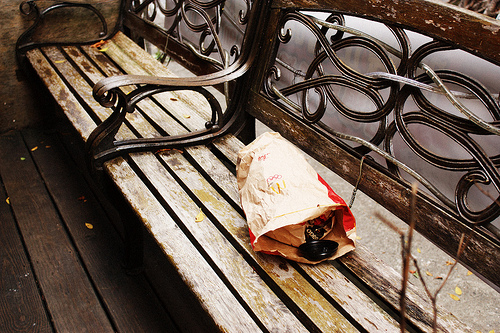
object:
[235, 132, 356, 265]
bag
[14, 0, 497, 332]
bench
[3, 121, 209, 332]
porch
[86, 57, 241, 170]
arm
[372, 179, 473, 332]
twigs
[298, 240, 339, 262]
coffee lid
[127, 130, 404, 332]
slats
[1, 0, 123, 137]
wall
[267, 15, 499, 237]
lighting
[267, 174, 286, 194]
logo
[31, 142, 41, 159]
cigarette butt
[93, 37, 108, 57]
leaf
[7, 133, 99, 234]
leaves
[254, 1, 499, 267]
back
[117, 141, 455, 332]
seat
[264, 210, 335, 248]
wrapper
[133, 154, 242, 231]
scratches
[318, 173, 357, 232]
sign